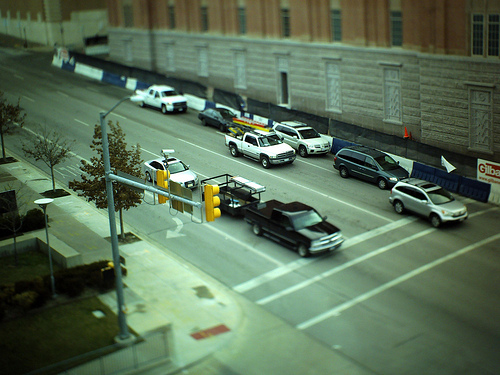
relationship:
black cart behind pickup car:
[201, 171, 267, 218] [241, 197, 348, 258]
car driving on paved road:
[333, 143, 411, 192] [377, 223, 496, 295]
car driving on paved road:
[271, 119, 334, 158] [307, 231, 493, 364]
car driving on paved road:
[264, 136, 307, 197] [216, 262, 400, 344]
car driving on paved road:
[241, 197, 348, 258] [253, 306, 380, 375]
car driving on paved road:
[143, 155, 200, 191] [269, 263, 377, 312]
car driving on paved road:
[198, 107, 239, 133] [306, 284, 402, 375]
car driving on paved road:
[128, 83, 189, 115] [359, 214, 402, 259]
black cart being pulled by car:
[201, 171, 267, 218] [241, 197, 348, 258]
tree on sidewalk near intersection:
[64, 113, 151, 242] [202, 277, 253, 375]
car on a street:
[241, 197, 348, 258] [332, 233, 438, 336]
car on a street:
[198, 107, 239, 133] [361, 237, 436, 341]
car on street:
[141, 155, 200, 200] [5, 29, 495, 372]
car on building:
[128, 83, 189, 115] [100, 2, 498, 178]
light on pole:
[126, 92, 147, 103] [92, 108, 140, 343]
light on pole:
[198, 179, 222, 222] [107, 173, 202, 208]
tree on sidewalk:
[17, 119, 78, 194] [6, 143, 256, 373]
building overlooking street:
[105, 7, 498, 166] [5, 29, 495, 372]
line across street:
[296, 230, 497, 329] [5, 29, 495, 372]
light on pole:
[126, 87, 146, 105] [97, 108, 134, 346]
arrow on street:
[160, 211, 190, 246] [5, 29, 495, 372]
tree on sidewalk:
[64, 113, 152, 236] [6, 143, 256, 373]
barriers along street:
[65, 50, 498, 209] [5, 29, 495, 372]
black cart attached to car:
[201, 171, 267, 218] [241, 197, 348, 258]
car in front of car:
[241, 192, 345, 261] [143, 155, 200, 191]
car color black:
[241, 197, 348, 258] [275, 200, 295, 216]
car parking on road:
[132, 74, 196, 120] [45, 99, 228, 161]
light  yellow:
[200, 182, 222, 224] [207, 191, 213, 214]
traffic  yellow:
[150, 160, 178, 204] [153, 169, 166, 188]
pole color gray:
[90, 99, 153, 349] [107, 199, 120, 229]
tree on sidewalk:
[25, 129, 74, 209] [31, 161, 121, 236]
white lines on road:
[362, 221, 432, 291] [264, 189, 484, 358]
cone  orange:
[398, 115, 419, 147] [400, 126, 414, 136]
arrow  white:
[166, 217, 187, 239] [165, 226, 178, 239]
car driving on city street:
[128, 83, 189, 115] [78, 84, 212, 152]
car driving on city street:
[199, 100, 242, 128] [154, 115, 244, 169]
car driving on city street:
[271, 119, 334, 158] [275, 145, 389, 232]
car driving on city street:
[224, 129, 298, 170] [189, 144, 340, 217]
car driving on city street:
[143, 155, 200, 191] [112, 107, 242, 182]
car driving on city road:
[241, 197, 348, 258] [0, 37, 500, 375]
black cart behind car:
[201, 167, 267, 217] [241, 197, 348, 258]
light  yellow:
[200, 182, 222, 224] [205, 183, 215, 210]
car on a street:
[241, 192, 345, 261] [5, 29, 495, 372]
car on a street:
[331, 141, 411, 188] [5, 29, 495, 372]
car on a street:
[269, 116, 333, 159] [5, 29, 495, 372]